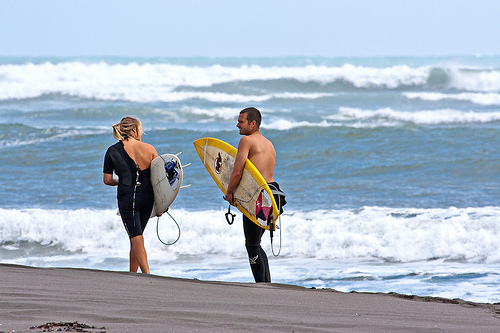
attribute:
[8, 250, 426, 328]
sea shore — holding surfboards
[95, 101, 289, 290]
man/woman — holding surfboards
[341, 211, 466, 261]
wave — gentle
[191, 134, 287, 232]
surfboard — yellow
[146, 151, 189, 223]
surfboard — white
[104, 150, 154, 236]
wetsuit — black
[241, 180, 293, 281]
pants — wet, black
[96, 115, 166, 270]
woman — blonde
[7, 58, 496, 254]
ocean — white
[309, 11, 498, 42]
sky — blue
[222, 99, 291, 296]
man — light skinned